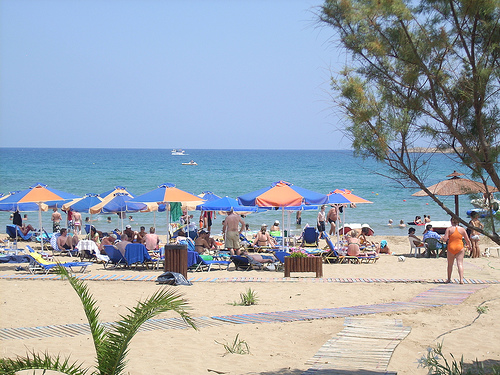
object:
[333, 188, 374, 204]
orange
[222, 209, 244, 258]
man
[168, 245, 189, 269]
wooden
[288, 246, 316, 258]
plant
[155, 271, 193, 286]
trash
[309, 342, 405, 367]
wood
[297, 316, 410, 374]
sidewalk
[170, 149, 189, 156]
white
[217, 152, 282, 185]
water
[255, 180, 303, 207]
orange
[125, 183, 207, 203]
umbrella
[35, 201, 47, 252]
wooden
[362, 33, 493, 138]
tree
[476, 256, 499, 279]
ground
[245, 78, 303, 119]
right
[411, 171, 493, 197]
brown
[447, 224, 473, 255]
suit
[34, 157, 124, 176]
ocean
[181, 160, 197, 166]
boat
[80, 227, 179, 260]
people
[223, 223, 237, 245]
shorts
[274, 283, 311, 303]
sand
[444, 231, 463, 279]
woman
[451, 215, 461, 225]
hair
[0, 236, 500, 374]
beach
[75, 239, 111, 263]
towel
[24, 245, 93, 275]
chair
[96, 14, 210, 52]
blue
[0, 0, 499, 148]
sky